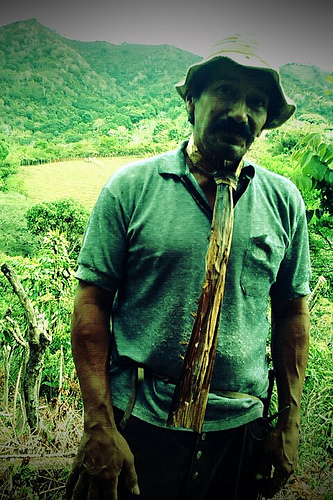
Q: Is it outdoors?
A: Yes, it is outdoors.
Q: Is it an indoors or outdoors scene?
A: It is outdoors.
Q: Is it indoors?
A: No, it is outdoors.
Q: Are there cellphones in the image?
A: No, there are no cellphones.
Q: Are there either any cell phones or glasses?
A: No, there are no cell phones or glasses.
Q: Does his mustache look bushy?
A: Yes, the moustache is bushy.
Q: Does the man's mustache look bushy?
A: Yes, the moustache is bushy.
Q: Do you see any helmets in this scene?
A: No, there are no helmets.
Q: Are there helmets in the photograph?
A: No, there are no helmets.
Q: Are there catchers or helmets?
A: No, there are no helmets or catchers.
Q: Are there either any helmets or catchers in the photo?
A: No, there are no helmets or catchers.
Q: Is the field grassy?
A: Yes, the field is grassy.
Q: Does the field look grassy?
A: Yes, the field is grassy.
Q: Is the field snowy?
A: No, the field is grassy.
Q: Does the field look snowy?
A: No, the field is grassy.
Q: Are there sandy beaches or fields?
A: No, there is a field but it is grassy.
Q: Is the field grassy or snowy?
A: The field is grassy.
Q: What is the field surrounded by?
A: The field is surrounded by the mountains.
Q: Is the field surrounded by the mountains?
A: Yes, the field is surrounded by the mountains.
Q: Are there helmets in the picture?
A: No, there are no helmets.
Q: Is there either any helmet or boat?
A: No, there are no helmets or boats.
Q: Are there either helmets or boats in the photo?
A: No, there are no helmets or boats.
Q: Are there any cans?
A: No, there are no cans.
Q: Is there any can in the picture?
A: No, there are no cans.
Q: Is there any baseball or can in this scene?
A: No, there are no cans or baseballs.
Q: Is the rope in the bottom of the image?
A: Yes, the rope is in the bottom of the image.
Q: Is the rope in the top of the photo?
A: No, the rope is in the bottom of the image.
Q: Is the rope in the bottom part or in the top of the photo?
A: The rope is in the bottom of the image.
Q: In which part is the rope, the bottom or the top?
A: The rope is in the bottom of the image.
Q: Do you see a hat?
A: Yes, there is a hat.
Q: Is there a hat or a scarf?
A: Yes, there is a hat.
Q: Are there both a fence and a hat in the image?
A: No, there is a hat but no fences.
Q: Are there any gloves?
A: No, there are no gloves.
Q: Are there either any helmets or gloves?
A: No, there are no gloves or helmets.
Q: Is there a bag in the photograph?
A: No, there are no bags.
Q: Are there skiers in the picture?
A: No, there are no skiers.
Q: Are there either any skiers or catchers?
A: No, there are no skiers or catchers.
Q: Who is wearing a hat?
A: The man is wearing a hat.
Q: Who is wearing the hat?
A: The man is wearing a hat.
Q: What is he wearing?
A: The man is wearing a hat.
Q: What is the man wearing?
A: The man is wearing a hat.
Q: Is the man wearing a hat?
A: Yes, the man is wearing a hat.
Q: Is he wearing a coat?
A: No, the man is wearing a hat.